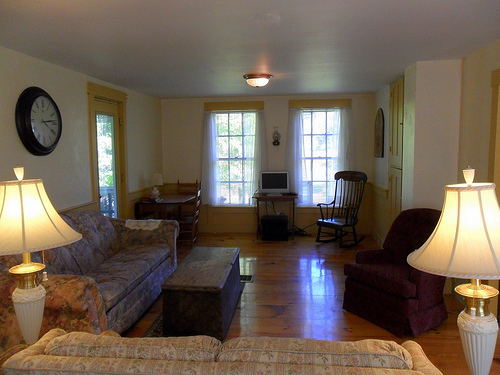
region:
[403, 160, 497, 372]
The lamp is white and gold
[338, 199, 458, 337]
The chair is purple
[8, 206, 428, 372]
The couches are tan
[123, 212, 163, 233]
White cloth on couch arm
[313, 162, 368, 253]
The arm chair is dark wood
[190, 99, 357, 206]
White curtains on the windows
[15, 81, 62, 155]
Black clock on wall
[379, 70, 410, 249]
The door is yellow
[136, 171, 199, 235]
Table with books and a lamp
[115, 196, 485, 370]
The floor is wood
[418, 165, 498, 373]
a table lamp to the right of the couch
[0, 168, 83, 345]
a table lamp to the left of the couch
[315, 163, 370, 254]
a rocking chair next to the window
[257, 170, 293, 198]
a computer between the windows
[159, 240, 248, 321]
a coffee table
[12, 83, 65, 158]
a clock on the wall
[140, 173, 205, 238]
a table and chairs in the corner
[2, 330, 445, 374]
a two cushioned couch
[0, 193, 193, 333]
a two cushioned couch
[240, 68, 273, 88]
a bright ceiling light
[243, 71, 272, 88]
an illuminated half-circular ceiling light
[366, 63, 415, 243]
two yellow doors on top of each other that are flush with the wall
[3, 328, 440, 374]
a loveseat with a floral striped pattern seen from behind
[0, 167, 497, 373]
two identical lamps that are on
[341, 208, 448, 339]
a dark maroon easy chair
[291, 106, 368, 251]
wooden rocking chair next to a window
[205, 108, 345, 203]
computer monitor between two windows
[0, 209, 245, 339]
couch behind a coffee table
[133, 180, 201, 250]
wooden chairs around a table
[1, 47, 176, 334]
large round clock on wall above couch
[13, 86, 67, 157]
The clock on the wall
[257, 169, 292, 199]
The television on the small table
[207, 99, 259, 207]
The window to the left of the television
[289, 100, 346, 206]
The window to the right of the television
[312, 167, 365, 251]
A wooden rocking chair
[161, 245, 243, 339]
A wooden coffee table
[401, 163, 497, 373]
The lamp on the right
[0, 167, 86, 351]
The lamp on the left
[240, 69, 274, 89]
The light on the ceiling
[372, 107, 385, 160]
A piece of wall art shaped like a stone tablet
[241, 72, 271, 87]
A domed ceiling light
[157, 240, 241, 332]
A wooden living room table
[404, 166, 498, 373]
A white table lamp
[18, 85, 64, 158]
A brown wooden wall clock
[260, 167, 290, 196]
A small flat screen tv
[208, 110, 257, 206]
An large living room window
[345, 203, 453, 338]
A brown plush easy chiar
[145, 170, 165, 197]
A small table lamp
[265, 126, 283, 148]
A wall mounted lamp